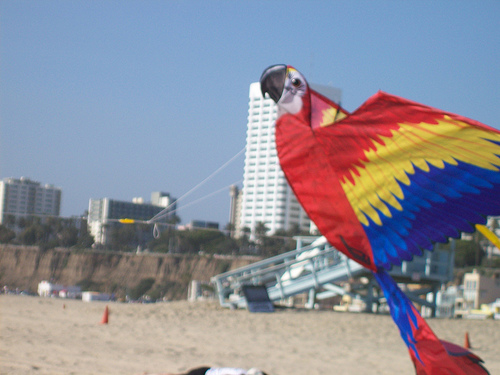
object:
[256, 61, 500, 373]
kite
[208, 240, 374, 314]
ramp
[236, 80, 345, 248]
building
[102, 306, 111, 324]
cone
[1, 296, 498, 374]
sand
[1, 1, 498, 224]
sky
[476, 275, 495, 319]
wall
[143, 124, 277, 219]
strings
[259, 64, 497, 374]
parrot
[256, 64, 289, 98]
beak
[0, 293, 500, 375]
beach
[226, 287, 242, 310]
people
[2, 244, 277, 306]
cliff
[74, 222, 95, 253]
trees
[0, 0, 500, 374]
background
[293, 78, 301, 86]
bird's eye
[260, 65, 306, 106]
bird's face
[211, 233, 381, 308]
walkway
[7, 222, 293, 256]
shrubbery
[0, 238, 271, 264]
fence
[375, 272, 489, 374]
tail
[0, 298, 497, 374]
dirt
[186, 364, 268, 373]
person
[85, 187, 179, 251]
building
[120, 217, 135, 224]
yellow object